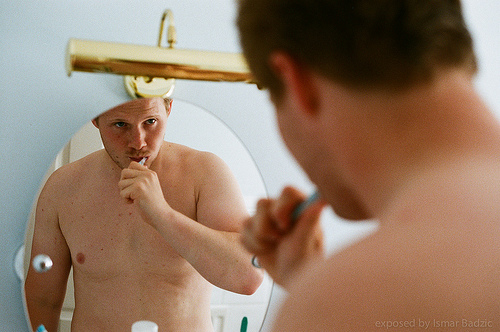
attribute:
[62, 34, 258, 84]
light — golden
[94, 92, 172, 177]
face — focused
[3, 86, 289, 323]
man — light skinned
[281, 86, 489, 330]
man — bare chested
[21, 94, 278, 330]
mirror — round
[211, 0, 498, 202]
man's head — back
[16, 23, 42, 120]
wall — white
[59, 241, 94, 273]
nipple — man's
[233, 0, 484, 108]
hair — short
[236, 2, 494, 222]
head — mans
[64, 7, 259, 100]
light — gold